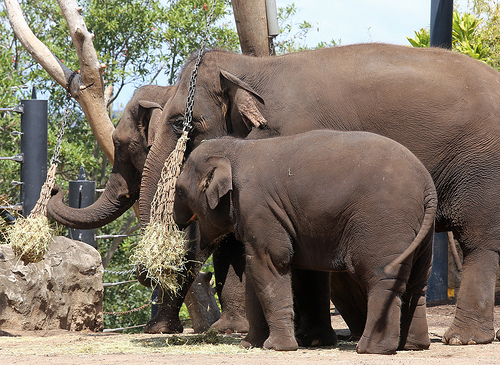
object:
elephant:
[174, 127, 439, 355]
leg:
[247, 247, 300, 352]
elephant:
[139, 40, 500, 346]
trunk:
[139, 129, 183, 230]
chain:
[31, 71, 77, 215]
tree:
[0, 0, 119, 164]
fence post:
[20, 99, 49, 220]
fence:
[0, 101, 155, 334]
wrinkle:
[269, 196, 299, 247]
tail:
[382, 171, 438, 278]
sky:
[0, 0, 500, 103]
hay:
[127, 216, 197, 291]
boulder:
[0, 234, 106, 337]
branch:
[52, 0, 105, 94]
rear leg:
[440, 215, 499, 346]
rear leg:
[351, 236, 410, 354]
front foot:
[262, 305, 299, 350]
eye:
[171, 184, 187, 201]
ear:
[201, 155, 233, 211]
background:
[0, 0, 500, 184]